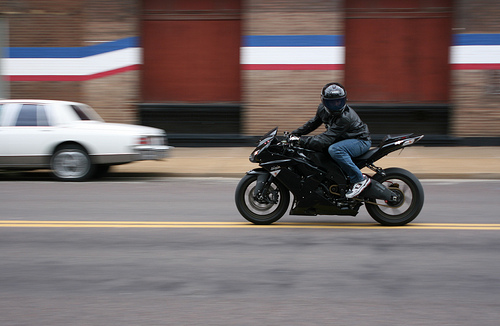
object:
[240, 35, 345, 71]
strip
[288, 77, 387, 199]
man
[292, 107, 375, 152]
black jacket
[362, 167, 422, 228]
wheel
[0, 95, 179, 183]
car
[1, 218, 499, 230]
line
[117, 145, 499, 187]
sidewalk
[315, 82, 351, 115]
helmet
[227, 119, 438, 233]
motorcycle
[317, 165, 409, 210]
chain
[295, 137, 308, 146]
gloves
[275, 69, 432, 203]
person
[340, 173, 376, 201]
sneakers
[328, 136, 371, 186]
jeans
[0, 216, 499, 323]
street